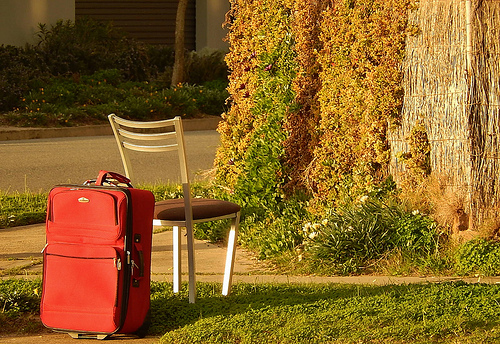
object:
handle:
[132, 234, 144, 287]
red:
[129, 239, 142, 251]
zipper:
[41, 184, 133, 334]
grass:
[0, 184, 220, 225]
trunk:
[392, 0, 498, 245]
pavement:
[43, 147, 75, 172]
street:
[0, 131, 92, 198]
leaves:
[219, 0, 288, 20]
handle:
[82, 177, 119, 188]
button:
[133, 278, 140, 288]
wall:
[3, 4, 66, 37]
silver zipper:
[40, 243, 50, 254]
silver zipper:
[113, 257, 122, 270]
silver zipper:
[130, 259, 139, 274]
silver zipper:
[124, 235, 127, 251]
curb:
[1, 114, 224, 144]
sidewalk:
[3, 111, 228, 142]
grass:
[3, 70, 221, 126]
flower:
[149, 110, 155, 113]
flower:
[35, 107, 40, 112]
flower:
[177, 82, 181, 87]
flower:
[65, 119, 70, 124]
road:
[1, 125, 220, 190]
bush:
[31, 17, 146, 77]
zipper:
[113, 251, 123, 306]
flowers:
[354, 192, 384, 211]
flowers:
[297, 205, 357, 253]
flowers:
[399, 202, 430, 225]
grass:
[252, 192, 433, 262]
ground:
[157, 299, 469, 339]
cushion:
[152, 198, 238, 222]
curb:
[4, 168, 240, 220]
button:
[134, 233, 141, 242]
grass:
[173, 282, 482, 342]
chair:
[105, 114, 243, 306]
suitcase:
[37, 169, 155, 339]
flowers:
[154, 82, 199, 108]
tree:
[212, 0, 500, 245]